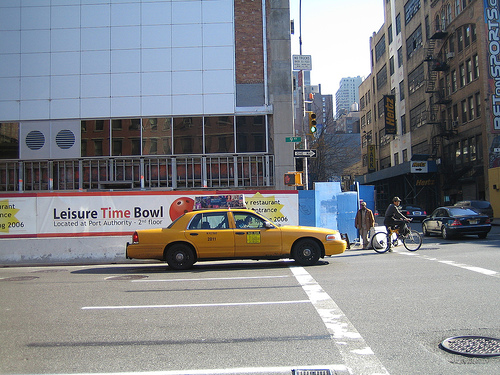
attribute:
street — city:
[0, 217, 499, 372]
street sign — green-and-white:
[285, 135, 305, 144]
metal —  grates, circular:
[425, 300, 499, 373]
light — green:
[301, 109, 317, 142]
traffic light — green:
[305, 108, 321, 138]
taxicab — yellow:
[125, 202, 345, 267]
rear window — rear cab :
[200, 212, 230, 231]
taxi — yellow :
[124, 196, 349, 271]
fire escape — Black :
[417, 27, 457, 167]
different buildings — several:
[283, 1, 498, 225]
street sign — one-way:
[294, 148, 315, 159]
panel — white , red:
[40, 179, 237, 256]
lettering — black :
[45, 198, 164, 222]